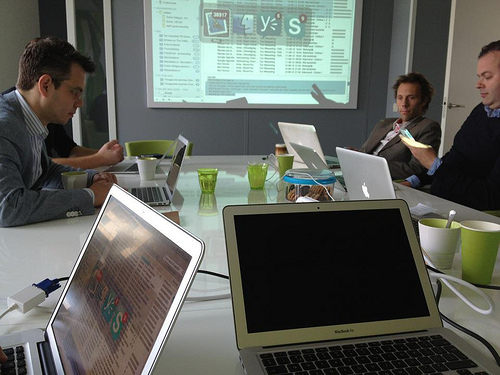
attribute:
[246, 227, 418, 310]
screen — black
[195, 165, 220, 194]
cup — green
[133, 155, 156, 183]
cup —  white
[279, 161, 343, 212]
tupperware — full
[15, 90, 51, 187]
shirt — striped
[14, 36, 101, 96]
brown hair — is brown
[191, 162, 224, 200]
glass — green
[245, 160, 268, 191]
glass — one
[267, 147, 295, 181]
mug — green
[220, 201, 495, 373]
laptop — one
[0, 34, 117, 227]
man — looking, one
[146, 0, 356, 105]
projection — screened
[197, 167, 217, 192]
glass — green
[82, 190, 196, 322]
laptop — one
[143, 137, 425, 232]
table — one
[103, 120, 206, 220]
laptop — one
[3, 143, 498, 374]
table — one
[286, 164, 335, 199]
bowl — one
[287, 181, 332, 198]
cookies — some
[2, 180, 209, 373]
laptop — reflective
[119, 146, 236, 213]
chair — office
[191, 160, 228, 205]
glass — green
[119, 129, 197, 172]
back — green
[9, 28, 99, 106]
hair — short